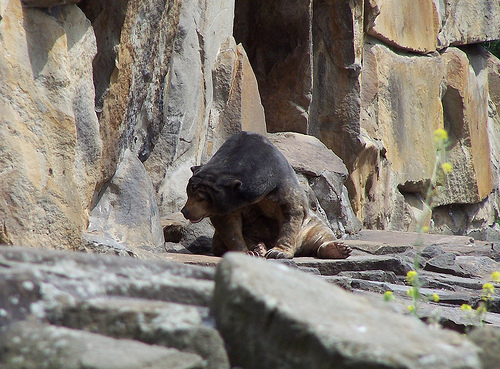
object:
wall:
[0, 0, 500, 253]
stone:
[40, 144, 89, 260]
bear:
[180, 129, 353, 259]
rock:
[0, 0, 497, 367]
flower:
[0, 228, 500, 369]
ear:
[217, 175, 243, 188]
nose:
[180, 209, 190, 217]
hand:
[244, 251, 261, 258]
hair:
[192, 166, 226, 185]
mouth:
[184, 214, 205, 223]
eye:
[196, 196, 204, 202]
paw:
[320, 241, 352, 259]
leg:
[210, 212, 248, 254]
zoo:
[0, 0, 500, 367]